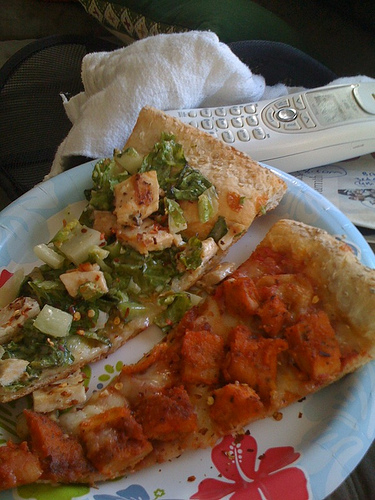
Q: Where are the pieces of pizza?
A: On the plate.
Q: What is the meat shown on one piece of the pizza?
A: Chicken.